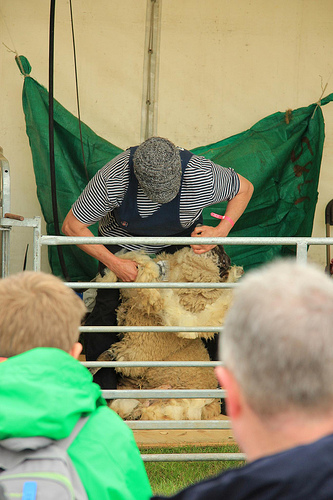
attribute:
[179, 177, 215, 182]
stripe — blue, white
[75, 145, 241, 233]
shirt — striped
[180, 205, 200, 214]
stripe — blue, striped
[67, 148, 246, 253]
shirt — white, striped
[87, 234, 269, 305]
wool — coarse, brown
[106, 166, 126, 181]
stripe — blue, striped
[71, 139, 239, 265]
shirt — white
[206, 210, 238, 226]
band — pink and white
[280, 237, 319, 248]
bar — metal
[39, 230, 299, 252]
bar — metal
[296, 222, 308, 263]
bar — metal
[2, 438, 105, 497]
backpack — gray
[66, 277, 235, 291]
bar — metal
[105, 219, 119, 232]
stripe — striped, blue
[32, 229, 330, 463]
gate — silver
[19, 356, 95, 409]
sweatshirt — green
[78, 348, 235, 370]
bar — metal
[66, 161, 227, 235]
shirt — striped, white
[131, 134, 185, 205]
cap — small, gray, wool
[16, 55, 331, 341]
fabric — green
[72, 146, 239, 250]
shirt — blue, white, striped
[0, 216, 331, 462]
iron railing — tall silver iron 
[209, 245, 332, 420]
hair — gray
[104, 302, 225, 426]
gate — metal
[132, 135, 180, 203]
hat — gray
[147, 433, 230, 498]
ground — grassy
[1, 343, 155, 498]
jacket — green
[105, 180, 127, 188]
stripe — blue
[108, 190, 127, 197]
stripe — blue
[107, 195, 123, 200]
stripe — blue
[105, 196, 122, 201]
stripe — blue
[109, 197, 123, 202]
stripe — blue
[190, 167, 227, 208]
stripe — blue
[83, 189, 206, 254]
shirt — white, stripe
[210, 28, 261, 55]
spots — small, black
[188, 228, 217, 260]
hand — man's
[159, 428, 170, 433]
stone — small